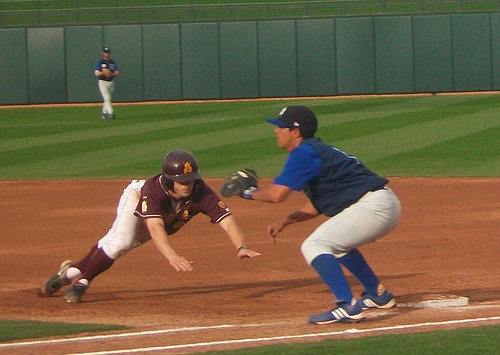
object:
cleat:
[354, 292, 394, 310]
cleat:
[306, 304, 363, 326]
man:
[41, 150, 262, 303]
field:
[0, 91, 500, 353]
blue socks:
[308, 253, 354, 303]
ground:
[403, 111, 476, 172]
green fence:
[1, 12, 498, 104]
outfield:
[0, 92, 500, 178]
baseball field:
[0, 93, 500, 354]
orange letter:
[182, 162, 194, 175]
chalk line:
[0, 299, 500, 352]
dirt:
[0, 177, 500, 355]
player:
[92, 47, 119, 120]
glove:
[220, 168, 259, 199]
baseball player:
[220, 105, 405, 325]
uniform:
[97, 165, 235, 262]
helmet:
[162, 149, 203, 182]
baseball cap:
[263, 104, 318, 139]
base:
[392, 290, 467, 312]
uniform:
[268, 134, 410, 298]